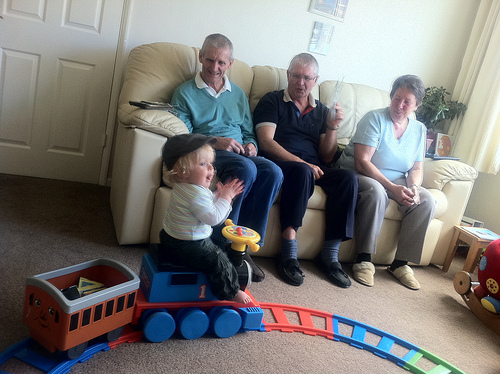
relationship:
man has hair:
[167, 34, 283, 284] [198, 30, 233, 63]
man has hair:
[254, 53, 357, 291] [286, 50, 320, 77]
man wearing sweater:
[167, 34, 283, 284] [167, 78, 258, 150]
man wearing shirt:
[167, 34, 283, 284] [194, 69, 232, 96]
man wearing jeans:
[167, 34, 283, 284] [212, 144, 284, 250]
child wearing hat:
[158, 130, 252, 303] [161, 130, 216, 169]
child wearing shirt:
[158, 130, 252, 303] [161, 183, 231, 241]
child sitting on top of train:
[158, 130, 252, 303] [22, 217, 263, 360]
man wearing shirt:
[254, 53, 357, 291] [251, 88, 328, 169]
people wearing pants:
[335, 73, 435, 290] [354, 174, 433, 266]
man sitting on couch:
[167, 34, 283, 284] [106, 40, 479, 266]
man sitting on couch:
[254, 53, 357, 291] [106, 40, 479, 266]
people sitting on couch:
[335, 73, 435, 290] [106, 40, 479, 266]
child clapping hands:
[158, 130, 252, 303] [213, 178, 243, 202]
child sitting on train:
[158, 130, 252, 303] [22, 217, 263, 360]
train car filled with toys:
[22, 256, 140, 359] [60, 276, 104, 302]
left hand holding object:
[324, 99, 345, 129] [330, 82, 337, 120]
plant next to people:
[413, 85, 467, 135] [335, 73, 435, 290]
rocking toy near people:
[450, 234, 498, 337] [335, 73, 435, 290]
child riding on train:
[158, 130, 252, 303] [22, 217, 263, 360]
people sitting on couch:
[170, 32, 433, 290] [106, 40, 479, 266]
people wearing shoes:
[170, 32, 433, 290] [245, 252, 422, 291]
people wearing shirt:
[335, 73, 435, 290] [334, 108, 427, 184]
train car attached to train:
[22, 256, 140, 359] [22, 217, 263, 360]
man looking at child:
[167, 34, 283, 284] [158, 130, 252, 303]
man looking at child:
[254, 53, 357, 291] [158, 130, 252, 303]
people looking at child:
[335, 73, 435, 290] [158, 130, 252, 303]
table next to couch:
[440, 224, 499, 274] [106, 40, 479, 266]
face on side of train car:
[24, 292, 59, 334] [22, 256, 140, 359]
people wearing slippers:
[335, 73, 435, 290] [351, 260, 421, 291]